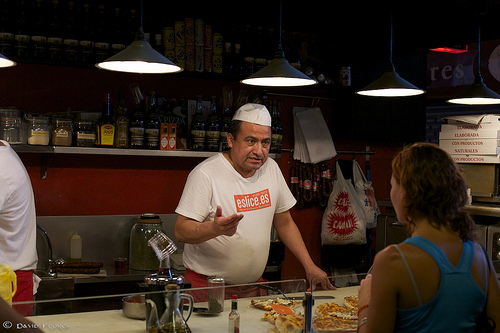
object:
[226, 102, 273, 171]
head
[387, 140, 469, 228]
head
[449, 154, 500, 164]
boxes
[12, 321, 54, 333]
name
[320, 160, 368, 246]
bags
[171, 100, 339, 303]
cook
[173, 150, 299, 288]
shirt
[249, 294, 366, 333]
pizza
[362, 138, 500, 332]
lady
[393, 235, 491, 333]
blue tank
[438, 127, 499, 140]
boxes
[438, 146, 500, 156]
boxes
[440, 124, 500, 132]
boxes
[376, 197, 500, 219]
shelf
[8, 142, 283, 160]
shelf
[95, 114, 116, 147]
spices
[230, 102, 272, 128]
hat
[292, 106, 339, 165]
sheet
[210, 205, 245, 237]
hand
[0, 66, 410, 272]
wall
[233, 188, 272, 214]
symbol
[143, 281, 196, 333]
bottle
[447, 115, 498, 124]
boxes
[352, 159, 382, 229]
bags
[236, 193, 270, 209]
word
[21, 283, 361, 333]
table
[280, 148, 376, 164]
hook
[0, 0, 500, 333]
restaurant